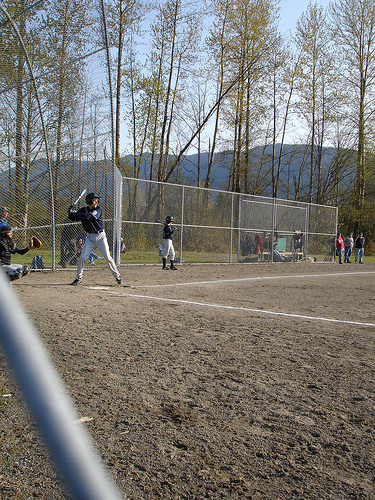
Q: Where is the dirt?
A: On the field.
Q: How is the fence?
A: Chain link.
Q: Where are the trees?
A: Behind the field.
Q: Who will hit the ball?
A: Player.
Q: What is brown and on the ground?
A: Dirt.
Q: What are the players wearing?
A: White pants and blue shirt.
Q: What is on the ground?
A: White chalk lines.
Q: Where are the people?
A: At baseball field.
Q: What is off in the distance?
A: Mountains.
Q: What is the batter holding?
A: A baseball bat.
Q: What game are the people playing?
A: Baseball.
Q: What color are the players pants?
A: White.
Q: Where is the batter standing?
A: Home plate.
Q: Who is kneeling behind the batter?
A: Catcher.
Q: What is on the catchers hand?
A: Mitt.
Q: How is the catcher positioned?
A: Kneeling.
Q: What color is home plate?
A: White.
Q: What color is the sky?
A: Blue.